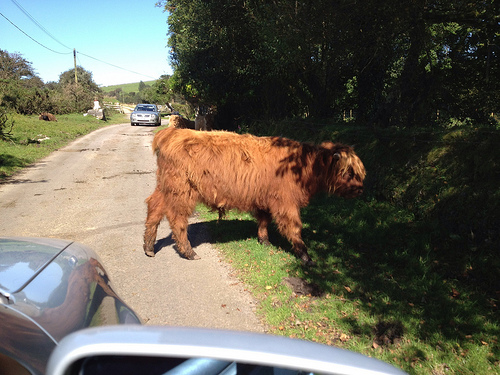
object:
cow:
[143, 128, 368, 260]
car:
[129, 103, 162, 128]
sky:
[87, 8, 124, 53]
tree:
[386, 0, 437, 130]